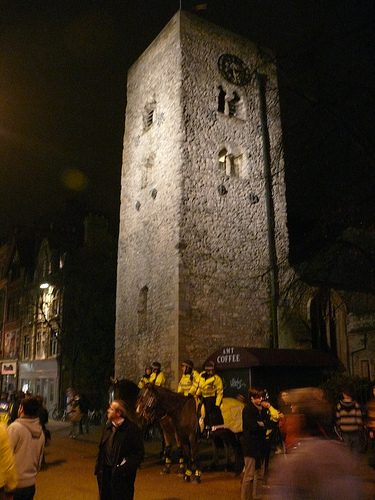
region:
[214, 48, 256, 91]
circle painted on the side of a tower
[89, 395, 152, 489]
man with a black jacket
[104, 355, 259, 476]
police in yellow jackets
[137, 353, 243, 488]
police in yellow on horses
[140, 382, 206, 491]
horses with yellow booties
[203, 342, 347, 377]
awning for a coffee shop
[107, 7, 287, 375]
stone tower in the night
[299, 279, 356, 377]
stone archway entrance to the tower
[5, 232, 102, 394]
old houses converted to stores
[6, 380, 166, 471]
crowd on the street at night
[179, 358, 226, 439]
Policeman riding on horses.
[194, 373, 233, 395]
The man has on a yellow jacket.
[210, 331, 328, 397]
The police officers are standing by the canopy.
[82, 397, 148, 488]
People standing and looking around.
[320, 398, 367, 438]
A person wearing a striped jacket.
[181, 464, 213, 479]
The horses have yellow objects around the legs.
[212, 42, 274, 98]
The concrete building has a clock on top.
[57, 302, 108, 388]
A tree is next to the building.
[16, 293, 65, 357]
Windows on the building.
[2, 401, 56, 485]
The man is wearing a hoodie.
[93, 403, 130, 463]
A man in black is visible.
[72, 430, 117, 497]
A man in black is visible.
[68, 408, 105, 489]
A man in black is visible.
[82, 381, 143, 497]
A man in black is visible.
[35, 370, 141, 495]
A man in black is visible.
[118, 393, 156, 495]
A man in black is visible.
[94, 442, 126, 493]
A man in black is visible.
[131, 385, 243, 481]
A horse is visible.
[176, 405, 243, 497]
A horse is visible.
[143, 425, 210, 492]
A horse is visible.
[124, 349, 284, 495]
A horse is visible.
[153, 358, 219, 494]
A horse is visible.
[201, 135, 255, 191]
window in the stone building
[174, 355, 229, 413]
men in yellow vests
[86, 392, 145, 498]
man in a coat standing on the street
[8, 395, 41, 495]
man in a white hooded sweatshirt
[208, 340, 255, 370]
a sign for coffee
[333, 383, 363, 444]
person wearing a striped sweatshirt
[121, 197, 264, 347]
a stone tower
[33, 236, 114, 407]
a dimly lit tree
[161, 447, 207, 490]
horses with reflective shoes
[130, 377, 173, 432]
the head of a horse